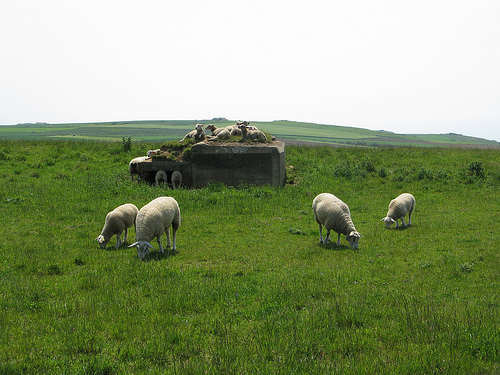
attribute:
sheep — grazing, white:
[308, 194, 368, 257]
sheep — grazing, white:
[378, 194, 413, 231]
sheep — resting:
[182, 116, 263, 145]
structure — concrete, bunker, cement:
[133, 138, 289, 193]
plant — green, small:
[119, 134, 134, 156]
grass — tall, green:
[12, 179, 499, 353]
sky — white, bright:
[4, 3, 498, 137]